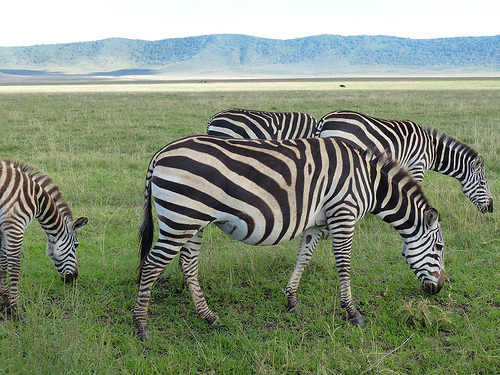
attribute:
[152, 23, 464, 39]
sky — blue 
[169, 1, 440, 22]
sky — white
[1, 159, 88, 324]
zebras — grazing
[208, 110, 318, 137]
zebras — grazing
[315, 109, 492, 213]
zebras — grazing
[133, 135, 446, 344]
zebras — grazing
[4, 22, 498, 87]
mountain — large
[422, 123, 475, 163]
mane — black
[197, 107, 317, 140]
zebra — feeding 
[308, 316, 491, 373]
grass — Green 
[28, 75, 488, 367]
grass — green 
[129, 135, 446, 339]
zebra — feeding , standing, stripped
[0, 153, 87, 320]
zebra — feeding , standing, stripped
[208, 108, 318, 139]
zebra — standing, stripped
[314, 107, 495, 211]
zebra — feeding , standing, stripped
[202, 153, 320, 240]
stripes — black, white